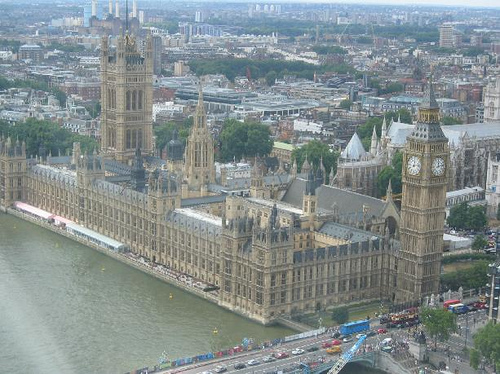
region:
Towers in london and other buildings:
[19, 10, 481, 362]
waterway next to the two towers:
[2, 214, 303, 369]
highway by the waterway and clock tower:
[140, 300, 487, 372]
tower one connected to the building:
[100, 31, 155, 152]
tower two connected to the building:
[399, 81, 454, 295]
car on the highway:
[291, 349, 305, 354]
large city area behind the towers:
[2, 1, 498, 163]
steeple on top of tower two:
[409, 81, 446, 141]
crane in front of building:
[331, 331, 371, 373]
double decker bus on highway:
[442, 298, 459, 309]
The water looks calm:
[24, 260, 132, 354]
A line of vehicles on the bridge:
[221, 345, 345, 372]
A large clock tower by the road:
[392, 83, 461, 310]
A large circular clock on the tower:
[398, 154, 430, 184]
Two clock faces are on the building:
[399, 150, 459, 185]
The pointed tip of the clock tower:
[415, 75, 450, 117]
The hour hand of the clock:
[434, 158, 439, 166]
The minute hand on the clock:
[437, 160, 445, 167]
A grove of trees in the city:
[182, 50, 347, 76]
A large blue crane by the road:
[327, 331, 371, 371]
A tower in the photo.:
[395, 77, 452, 299]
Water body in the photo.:
[33, 272, 148, 349]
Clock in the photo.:
[406, 150, 419, 180]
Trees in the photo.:
[219, 120, 269, 159]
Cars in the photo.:
[255, 349, 294, 364]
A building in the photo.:
[183, 217, 352, 302]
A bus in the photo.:
[341, 319, 373, 336]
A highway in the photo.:
[269, 319, 389, 366]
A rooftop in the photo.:
[192, 194, 222, 216]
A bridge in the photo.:
[341, 344, 398, 372]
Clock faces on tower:
[404, 154, 449, 181]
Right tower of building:
[386, 79, 452, 307]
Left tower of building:
[89, 26, 162, 163]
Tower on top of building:
[173, 79, 225, 187]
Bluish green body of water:
[0, 209, 301, 373]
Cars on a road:
[131, 289, 489, 373]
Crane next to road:
[317, 329, 384, 371]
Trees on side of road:
[415, 302, 498, 370]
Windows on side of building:
[25, 171, 401, 317]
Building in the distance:
[0, 2, 499, 218]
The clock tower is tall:
[396, 79, 447, 300]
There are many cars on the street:
[157, 282, 484, 369]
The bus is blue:
[331, 316, 374, 334]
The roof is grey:
[403, 77, 448, 147]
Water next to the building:
[5, 37, 443, 368]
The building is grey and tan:
[1, 39, 441, 314]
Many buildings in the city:
[14, 8, 498, 277]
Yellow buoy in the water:
[208, 321, 224, 338]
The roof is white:
[337, 115, 492, 189]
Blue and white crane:
[316, 333, 369, 372]